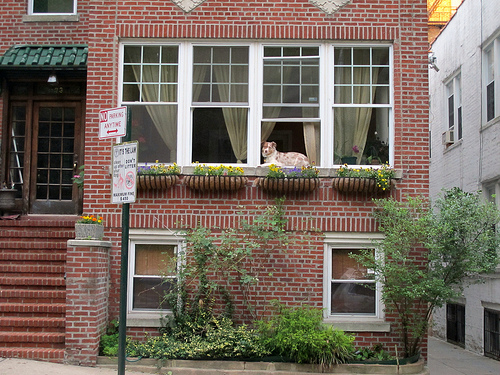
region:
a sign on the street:
[90, 103, 147, 373]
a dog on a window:
[251, 136, 318, 176]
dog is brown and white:
[260, 135, 314, 176]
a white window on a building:
[108, 35, 402, 182]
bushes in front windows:
[107, 213, 439, 364]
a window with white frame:
[311, 230, 387, 336]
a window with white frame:
[120, 225, 191, 331]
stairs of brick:
[3, 210, 68, 366]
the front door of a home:
[16, 82, 79, 217]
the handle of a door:
[68, 156, 86, 180]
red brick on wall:
[259, 255, 303, 293]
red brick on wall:
[273, 196, 308, 253]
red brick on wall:
[85, 295, 105, 315]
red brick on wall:
[85, 151, 120, 218]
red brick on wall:
[37, 301, 77, 338]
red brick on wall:
[47, 265, 107, 325]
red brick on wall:
[405, 160, 411, 180]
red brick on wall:
[400, 85, 405, 95]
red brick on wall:
[402, 42, 417, 63]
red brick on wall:
[377, 16, 407, 43]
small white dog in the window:
[261, 139, 306, 165]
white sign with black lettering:
[111, 140, 138, 199]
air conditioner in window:
[441, 128, 453, 145]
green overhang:
[1, 42, 86, 65]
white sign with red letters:
[97, 104, 127, 136]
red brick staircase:
[1, 213, 74, 355]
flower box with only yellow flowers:
[186, 162, 246, 189]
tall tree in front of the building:
[349, 185, 497, 362]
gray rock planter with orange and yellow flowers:
[73, 211, 104, 237]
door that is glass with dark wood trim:
[6, 96, 79, 210]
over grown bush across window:
[159, 214, 287, 339]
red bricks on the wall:
[265, 257, 295, 280]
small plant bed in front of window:
[95, 324, 425, 371]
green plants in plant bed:
[122, 317, 353, 356]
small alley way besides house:
[426, 302, 486, 352]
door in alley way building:
[435, 293, 477, 345]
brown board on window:
[125, 235, 194, 289]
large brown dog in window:
[246, 133, 353, 180]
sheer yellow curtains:
[125, 44, 215, 154]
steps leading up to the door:
[14, 210, 80, 346]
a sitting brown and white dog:
[259, 138, 307, 165]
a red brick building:
[5, 1, 427, 364]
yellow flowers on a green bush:
[125, 308, 253, 360]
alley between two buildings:
[423, 331, 499, 373]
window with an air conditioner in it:
[443, 72, 462, 146]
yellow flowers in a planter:
[333, 159, 395, 194]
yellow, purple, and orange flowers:
[256, 163, 321, 195]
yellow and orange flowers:
[73, 210, 105, 239]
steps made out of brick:
[0, 215, 67, 363]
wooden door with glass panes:
[8, 103, 80, 213]